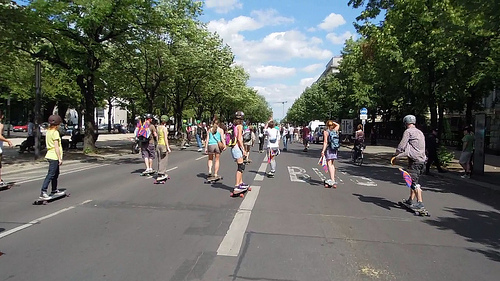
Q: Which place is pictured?
A: It is a road.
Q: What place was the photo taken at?
A: It was taken at the road.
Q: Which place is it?
A: It is a road.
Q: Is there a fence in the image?
A: No, there are no fences.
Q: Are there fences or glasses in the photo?
A: No, there are no fences or glasses.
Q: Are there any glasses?
A: No, there are no glasses.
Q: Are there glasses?
A: No, there are no glasses.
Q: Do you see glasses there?
A: No, there are no glasses.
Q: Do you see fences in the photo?
A: No, there are no fences.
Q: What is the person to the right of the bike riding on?
A: The person is riding on a skateboard.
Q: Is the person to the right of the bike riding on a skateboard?
A: Yes, the person is riding on a skateboard.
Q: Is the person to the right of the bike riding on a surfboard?
A: No, the person is riding on a skateboard.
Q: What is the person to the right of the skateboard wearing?
A: The person is wearing a helmet.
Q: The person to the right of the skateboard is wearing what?
A: The person is wearing a helmet.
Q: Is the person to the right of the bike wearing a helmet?
A: Yes, the person is wearing a helmet.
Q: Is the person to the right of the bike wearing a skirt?
A: No, the person is wearing a helmet.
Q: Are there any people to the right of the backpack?
A: Yes, there is a person to the right of the backpack.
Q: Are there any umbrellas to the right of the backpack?
A: No, there is a person to the right of the backpack.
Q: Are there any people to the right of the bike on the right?
A: Yes, there is a person to the right of the bike.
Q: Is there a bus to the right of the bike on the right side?
A: No, there is a person to the right of the bike.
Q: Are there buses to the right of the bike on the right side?
A: No, there is a person to the right of the bike.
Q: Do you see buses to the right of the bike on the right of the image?
A: No, there is a person to the right of the bike.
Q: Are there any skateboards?
A: Yes, there is a skateboard.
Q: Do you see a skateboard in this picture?
A: Yes, there is a skateboard.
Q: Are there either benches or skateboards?
A: Yes, there is a skateboard.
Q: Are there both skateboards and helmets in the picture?
A: Yes, there are both a skateboard and a helmet.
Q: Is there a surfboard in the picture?
A: No, there are no surfboards.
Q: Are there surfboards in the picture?
A: No, there are no surfboards.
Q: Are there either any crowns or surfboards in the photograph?
A: No, there are no surfboards or crowns.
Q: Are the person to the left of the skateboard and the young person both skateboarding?
A: Yes, both the person and the person are skateboarding.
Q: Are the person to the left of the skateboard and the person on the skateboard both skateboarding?
A: Yes, both the person and the person are skateboarding.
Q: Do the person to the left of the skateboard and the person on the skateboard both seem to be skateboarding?
A: Yes, both the person and the person are skateboarding.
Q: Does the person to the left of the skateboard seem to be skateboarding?
A: Yes, the person is skateboarding.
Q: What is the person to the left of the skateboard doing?
A: The person is skateboarding.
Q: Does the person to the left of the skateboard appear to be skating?
A: No, the person is skateboarding.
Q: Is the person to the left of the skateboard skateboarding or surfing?
A: The person is skateboarding.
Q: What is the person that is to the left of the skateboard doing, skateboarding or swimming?
A: The person is skateboarding.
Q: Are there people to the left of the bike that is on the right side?
A: Yes, there is a person to the left of the bike.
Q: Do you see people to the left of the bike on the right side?
A: Yes, there is a person to the left of the bike.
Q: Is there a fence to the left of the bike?
A: No, there is a person to the left of the bike.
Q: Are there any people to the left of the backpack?
A: Yes, there is a person to the left of the backpack.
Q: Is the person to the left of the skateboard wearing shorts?
A: Yes, the person is wearing shorts.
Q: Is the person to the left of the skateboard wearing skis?
A: No, the person is wearing shorts.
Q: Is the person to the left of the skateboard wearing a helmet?
A: Yes, the person is wearing a helmet.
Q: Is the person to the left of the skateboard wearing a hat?
A: No, the person is wearing a helmet.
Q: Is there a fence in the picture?
A: No, there are no fences.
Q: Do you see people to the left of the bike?
A: Yes, there is a person to the left of the bike.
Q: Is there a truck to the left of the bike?
A: No, there is a person to the left of the bike.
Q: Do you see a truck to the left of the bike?
A: No, there is a person to the left of the bike.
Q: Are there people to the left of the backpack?
A: Yes, there is a person to the left of the backpack.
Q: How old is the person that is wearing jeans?
A: The person is young.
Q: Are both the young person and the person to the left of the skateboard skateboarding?
A: Yes, both the person and the person are skateboarding.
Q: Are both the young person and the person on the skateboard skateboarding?
A: Yes, both the person and the person are skateboarding.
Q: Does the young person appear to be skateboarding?
A: Yes, the person is skateboarding.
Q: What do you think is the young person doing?
A: The person is skateboarding.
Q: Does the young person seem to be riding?
A: No, the person is skateboarding.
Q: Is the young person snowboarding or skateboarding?
A: The person is skateboarding.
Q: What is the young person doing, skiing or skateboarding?
A: The person is skateboarding.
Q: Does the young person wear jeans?
A: Yes, the person wears jeans.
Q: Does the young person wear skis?
A: No, the person wears jeans.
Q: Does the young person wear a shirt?
A: Yes, the person wears a shirt.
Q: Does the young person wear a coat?
A: No, the person wears a shirt.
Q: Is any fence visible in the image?
A: No, there are no fences.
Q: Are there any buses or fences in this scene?
A: No, there are no fences or buses.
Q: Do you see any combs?
A: No, there are no combs.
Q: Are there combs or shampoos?
A: No, there are no combs or shampoos.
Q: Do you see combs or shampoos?
A: No, there are no combs or shampoos.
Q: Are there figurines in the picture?
A: No, there are no figurines.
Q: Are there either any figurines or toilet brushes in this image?
A: No, there are no figurines or toilet brushes.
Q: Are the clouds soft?
A: Yes, the clouds are soft.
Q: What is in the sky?
A: The clouds are in the sky.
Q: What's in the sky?
A: The clouds are in the sky.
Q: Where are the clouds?
A: The clouds are in the sky.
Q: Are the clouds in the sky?
A: Yes, the clouds are in the sky.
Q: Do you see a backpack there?
A: Yes, there is a backpack.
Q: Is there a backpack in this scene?
A: Yes, there is a backpack.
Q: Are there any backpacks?
A: Yes, there is a backpack.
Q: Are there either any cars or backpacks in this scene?
A: Yes, there is a backpack.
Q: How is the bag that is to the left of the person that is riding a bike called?
A: The bag is a backpack.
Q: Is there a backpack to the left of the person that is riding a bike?
A: Yes, there is a backpack to the left of the person.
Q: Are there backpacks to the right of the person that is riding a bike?
A: No, the backpack is to the left of the person.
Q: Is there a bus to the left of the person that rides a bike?
A: No, there is a backpack to the left of the person.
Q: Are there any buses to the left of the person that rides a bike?
A: No, there is a backpack to the left of the person.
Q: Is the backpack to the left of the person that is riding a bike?
A: Yes, the backpack is to the left of the person.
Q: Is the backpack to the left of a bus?
A: No, the backpack is to the left of the person.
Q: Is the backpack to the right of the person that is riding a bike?
A: No, the backpack is to the left of the person.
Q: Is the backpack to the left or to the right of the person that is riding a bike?
A: The backpack is to the left of the person.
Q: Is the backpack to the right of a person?
A: Yes, the backpack is to the right of a person.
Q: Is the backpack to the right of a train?
A: No, the backpack is to the right of a person.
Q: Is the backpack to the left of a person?
A: No, the backpack is to the right of a person.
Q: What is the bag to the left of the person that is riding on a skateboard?
A: The bag is a backpack.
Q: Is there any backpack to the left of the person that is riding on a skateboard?
A: Yes, there is a backpack to the left of the person.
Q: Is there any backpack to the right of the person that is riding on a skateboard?
A: No, the backpack is to the left of the person.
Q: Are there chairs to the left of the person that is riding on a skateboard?
A: No, there is a backpack to the left of the person.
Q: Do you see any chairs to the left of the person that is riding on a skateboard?
A: No, there is a backpack to the left of the person.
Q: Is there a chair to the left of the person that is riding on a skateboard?
A: No, there is a backpack to the left of the person.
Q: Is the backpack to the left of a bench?
A: No, the backpack is to the left of the person.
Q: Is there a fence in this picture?
A: No, there are no fences.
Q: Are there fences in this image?
A: No, there are no fences.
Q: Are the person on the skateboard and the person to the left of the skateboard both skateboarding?
A: Yes, both the person and the person are skateboarding.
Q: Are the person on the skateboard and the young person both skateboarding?
A: Yes, both the person and the person are skateboarding.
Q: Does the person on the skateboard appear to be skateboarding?
A: Yes, the person is skateboarding.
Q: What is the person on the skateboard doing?
A: The person is skateboarding.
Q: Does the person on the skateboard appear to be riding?
A: No, the person is skateboarding.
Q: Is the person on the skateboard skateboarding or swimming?
A: The person is skateboarding.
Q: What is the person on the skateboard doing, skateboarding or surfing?
A: The person is skateboarding.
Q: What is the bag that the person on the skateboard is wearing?
A: The bag is a backpack.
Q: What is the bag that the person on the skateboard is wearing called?
A: The bag is a backpack.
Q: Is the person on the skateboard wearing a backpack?
A: Yes, the person is wearing a backpack.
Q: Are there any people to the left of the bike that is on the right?
A: Yes, there is a person to the left of the bike.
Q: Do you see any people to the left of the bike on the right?
A: Yes, there is a person to the left of the bike.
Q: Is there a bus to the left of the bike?
A: No, there is a person to the left of the bike.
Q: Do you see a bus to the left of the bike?
A: No, there is a person to the left of the bike.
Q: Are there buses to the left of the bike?
A: No, there is a person to the left of the bike.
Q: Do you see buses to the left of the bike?
A: No, there is a person to the left of the bike.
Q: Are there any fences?
A: No, there are no fences.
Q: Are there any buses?
A: No, there are no buses.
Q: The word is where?
A: The word is on the road.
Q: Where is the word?
A: The word is on the road.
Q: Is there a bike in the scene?
A: Yes, there is a bike.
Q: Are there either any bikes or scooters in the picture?
A: Yes, there is a bike.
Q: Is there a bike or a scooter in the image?
A: Yes, there is a bike.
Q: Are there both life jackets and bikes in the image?
A: No, there is a bike but no life jackets.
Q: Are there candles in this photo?
A: No, there are no candles.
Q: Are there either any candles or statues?
A: No, there are no candles or statues.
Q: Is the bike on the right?
A: Yes, the bike is on the right of the image.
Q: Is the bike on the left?
A: No, the bike is on the right of the image.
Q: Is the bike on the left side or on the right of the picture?
A: The bike is on the right of the image.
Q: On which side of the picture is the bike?
A: The bike is on the right of the image.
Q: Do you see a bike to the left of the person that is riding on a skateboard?
A: Yes, there is a bike to the left of the person.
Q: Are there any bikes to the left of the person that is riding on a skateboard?
A: Yes, there is a bike to the left of the person.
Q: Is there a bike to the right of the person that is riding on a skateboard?
A: No, the bike is to the left of the person.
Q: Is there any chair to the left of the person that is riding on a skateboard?
A: No, there is a bike to the left of the person.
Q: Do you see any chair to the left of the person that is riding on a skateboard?
A: No, there is a bike to the left of the person.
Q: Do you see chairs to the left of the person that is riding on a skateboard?
A: No, there is a bike to the left of the person.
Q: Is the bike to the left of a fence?
A: No, the bike is to the left of a person.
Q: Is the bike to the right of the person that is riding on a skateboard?
A: No, the bike is to the left of the person.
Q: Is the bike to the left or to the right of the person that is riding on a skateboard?
A: The bike is to the left of the person.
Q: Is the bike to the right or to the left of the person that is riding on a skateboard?
A: The bike is to the left of the person.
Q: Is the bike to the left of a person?
A: No, the bike is to the right of a person.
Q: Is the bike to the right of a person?
A: Yes, the bike is to the right of a person.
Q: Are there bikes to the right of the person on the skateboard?
A: Yes, there is a bike to the right of the person.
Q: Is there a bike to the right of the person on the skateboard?
A: Yes, there is a bike to the right of the person.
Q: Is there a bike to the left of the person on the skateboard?
A: No, the bike is to the right of the person.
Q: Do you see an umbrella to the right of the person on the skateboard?
A: No, there is a bike to the right of the person.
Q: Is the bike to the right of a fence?
A: No, the bike is to the right of a person.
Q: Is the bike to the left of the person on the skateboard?
A: No, the bike is to the right of the person.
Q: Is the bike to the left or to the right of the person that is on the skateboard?
A: The bike is to the right of the person.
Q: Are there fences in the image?
A: No, there are no fences.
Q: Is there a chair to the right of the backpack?
A: No, there is a person to the right of the backpack.